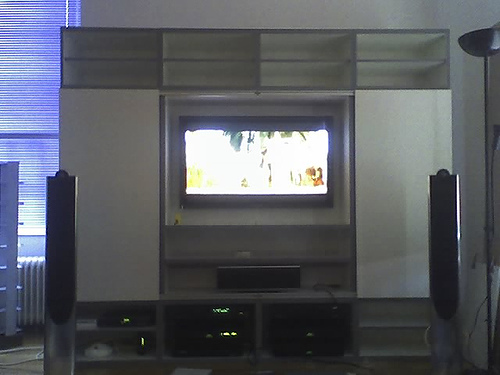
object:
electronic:
[180, 110, 335, 210]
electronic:
[93, 303, 160, 328]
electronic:
[137, 329, 152, 358]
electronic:
[174, 300, 251, 359]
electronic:
[267, 299, 349, 359]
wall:
[356, 92, 451, 295]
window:
[0, 2, 72, 236]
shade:
[0, 0, 79, 238]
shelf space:
[59, 27, 451, 90]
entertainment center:
[47, 24, 464, 374]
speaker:
[218, 266, 301, 290]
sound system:
[45, 169, 462, 375]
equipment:
[219, 254, 302, 293]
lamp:
[447, 27, 498, 371]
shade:
[456, 29, 499, 56]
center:
[44, 26, 464, 356]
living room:
[1, 1, 499, 372]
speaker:
[429, 169, 463, 375]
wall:
[61, 93, 157, 302]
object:
[0, 161, 24, 346]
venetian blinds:
[0, 0, 85, 237]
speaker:
[40, 170, 77, 373]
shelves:
[59, 28, 448, 90]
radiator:
[15, 257, 48, 330]